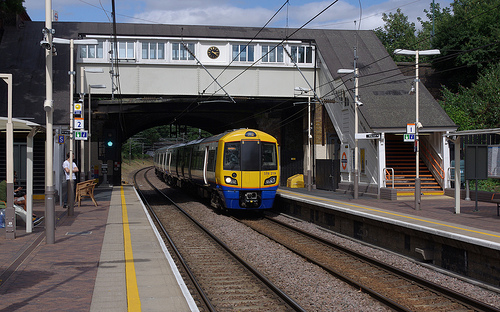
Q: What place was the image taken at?
A: It was taken at the train station.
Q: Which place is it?
A: It is a train station.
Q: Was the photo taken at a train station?
A: Yes, it was taken in a train station.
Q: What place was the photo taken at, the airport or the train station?
A: It was taken at the train station.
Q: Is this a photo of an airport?
A: No, the picture is showing a train station.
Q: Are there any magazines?
A: No, there are no magazines.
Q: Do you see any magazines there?
A: No, there are no magazines.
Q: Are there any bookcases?
A: No, there are no bookcases.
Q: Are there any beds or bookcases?
A: No, there are no bookcases or beds.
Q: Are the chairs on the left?
A: Yes, the chairs are on the left of the image.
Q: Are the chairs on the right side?
A: No, the chairs are on the left of the image.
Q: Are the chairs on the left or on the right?
A: The chairs are on the left of the image.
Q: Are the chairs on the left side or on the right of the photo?
A: The chairs are on the left of the image.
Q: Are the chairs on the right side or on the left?
A: The chairs are on the left of the image.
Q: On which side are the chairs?
A: The chairs are on the left of the image.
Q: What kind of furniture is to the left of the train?
A: The pieces of furniture are chairs.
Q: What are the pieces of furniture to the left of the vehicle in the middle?
A: The pieces of furniture are chairs.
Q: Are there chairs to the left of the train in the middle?
A: Yes, there are chairs to the left of the train.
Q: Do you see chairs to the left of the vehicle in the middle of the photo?
A: Yes, there are chairs to the left of the train.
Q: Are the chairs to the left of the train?
A: Yes, the chairs are to the left of the train.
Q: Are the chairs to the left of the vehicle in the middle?
A: Yes, the chairs are to the left of the train.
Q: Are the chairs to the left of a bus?
A: No, the chairs are to the left of the train.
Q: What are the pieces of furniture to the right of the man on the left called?
A: The pieces of furniture are chairs.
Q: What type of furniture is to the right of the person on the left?
A: The pieces of furniture are chairs.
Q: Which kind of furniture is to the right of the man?
A: The pieces of furniture are chairs.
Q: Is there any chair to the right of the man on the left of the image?
A: Yes, there are chairs to the right of the man.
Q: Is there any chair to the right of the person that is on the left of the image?
A: Yes, there are chairs to the right of the man.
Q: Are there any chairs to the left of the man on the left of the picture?
A: No, the chairs are to the right of the man.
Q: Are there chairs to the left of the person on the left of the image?
A: No, the chairs are to the right of the man.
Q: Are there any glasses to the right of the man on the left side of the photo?
A: No, there are chairs to the right of the man.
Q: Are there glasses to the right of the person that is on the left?
A: No, there are chairs to the right of the man.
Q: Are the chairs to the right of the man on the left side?
A: Yes, the chairs are to the right of the man.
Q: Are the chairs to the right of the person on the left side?
A: Yes, the chairs are to the right of the man.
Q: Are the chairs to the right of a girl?
A: No, the chairs are to the right of the man.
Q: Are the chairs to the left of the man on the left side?
A: No, the chairs are to the right of the man.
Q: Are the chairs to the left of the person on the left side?
A: No, the chairs are to the right of the man.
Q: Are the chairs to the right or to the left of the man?
A: The chairs are to the right of the man.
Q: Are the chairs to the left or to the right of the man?
A: The chairs are to the right of the man.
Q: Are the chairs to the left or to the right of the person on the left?
A: The chairs are to the right of the man.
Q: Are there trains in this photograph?
A: Yes, there is a train.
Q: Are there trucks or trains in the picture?
A: Yes, there is a train.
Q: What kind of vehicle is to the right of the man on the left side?
A: The vehicle is a train.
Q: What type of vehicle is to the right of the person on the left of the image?
A: The vehicle is a train.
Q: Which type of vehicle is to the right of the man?
A: The vehicle is a train.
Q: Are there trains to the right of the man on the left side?
A: Yes, there is a train to the right of the man.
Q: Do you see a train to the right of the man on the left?
A: Yes, there is a train to the right of the man.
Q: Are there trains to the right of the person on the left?
A: Yes, there is a train to the right of the man.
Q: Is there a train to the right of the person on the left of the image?
A: Yes, there is a train to the right of the man.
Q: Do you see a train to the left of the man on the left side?
A: No, the train is to the right of the man.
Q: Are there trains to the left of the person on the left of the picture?
A: No, the train is to the right of the man.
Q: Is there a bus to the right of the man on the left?
A: No, there is a train to the right of the man.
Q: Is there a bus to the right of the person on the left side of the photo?
A: No, there is a train to the right of the man.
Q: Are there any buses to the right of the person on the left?
A: No, there is a train to the right of the man.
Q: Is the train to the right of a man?
A: Yes, the train is to the right of a man.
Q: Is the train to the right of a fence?
A: No, the train is to the right of a man.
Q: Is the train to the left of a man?
A: No, the train is to the right of a man.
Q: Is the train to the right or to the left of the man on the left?
A: The train is to the right of the man.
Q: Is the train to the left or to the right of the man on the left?
A: The train is to the right of the man.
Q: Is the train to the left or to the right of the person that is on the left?
A: The train is to the right of the man.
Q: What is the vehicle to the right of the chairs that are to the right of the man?
A: The vehicle is a train.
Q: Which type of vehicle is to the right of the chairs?
A: The vehicle is a train.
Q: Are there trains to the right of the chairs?
A: Yes, there is a train to the right of the chairs.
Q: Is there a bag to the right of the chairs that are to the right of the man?
A: No, there is a train to the right of the chairs.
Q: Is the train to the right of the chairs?
A: Yes, the train is to the right of the chairs.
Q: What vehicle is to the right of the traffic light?
A: The vehicle is a train.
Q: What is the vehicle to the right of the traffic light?
A: The vehicle is a train.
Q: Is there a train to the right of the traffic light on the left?
A: Yes, there is a train to the right of the traffic signal.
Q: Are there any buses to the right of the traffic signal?
A: No, there is a train to the right of the traffic signal.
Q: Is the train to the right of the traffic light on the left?
A: Yes, the train is to the right of the traffic light.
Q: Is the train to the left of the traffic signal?
A: No, the train is to the right of the traffic signal.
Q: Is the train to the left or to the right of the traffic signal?
A: The train is to the right of the traffic signal.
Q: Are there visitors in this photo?
A: No, there are no visitors.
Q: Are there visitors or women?
A: No, there are no visitors or women.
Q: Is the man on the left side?
A: Yes, the man is on the left of the image.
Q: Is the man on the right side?
A: No, the man is on the left of the image.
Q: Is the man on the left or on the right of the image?
A: The man is on the left of the image.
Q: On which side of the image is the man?
A: The man is on the left of the image.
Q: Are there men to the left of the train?
A: Yes, there is a man to the left of the train.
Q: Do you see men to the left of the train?
A: Yes, there is a man to the left of the train.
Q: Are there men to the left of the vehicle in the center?
A: Yes, there is a man to the left of the train.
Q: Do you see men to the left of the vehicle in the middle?
A: Yes, there is a man to the left of the train.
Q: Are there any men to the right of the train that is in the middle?
A: No, the man is to the left of the train.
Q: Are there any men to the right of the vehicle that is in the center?
A: No, the man is to the left of the train.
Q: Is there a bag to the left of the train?
A: No, there is a man to the left of the train.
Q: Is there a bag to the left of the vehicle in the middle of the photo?
A: No, there is a man to the left of the train.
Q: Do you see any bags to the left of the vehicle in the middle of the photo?
A: No, there is a man to the left of the train.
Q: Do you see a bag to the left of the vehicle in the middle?
A: No, there is a man to the left of the train.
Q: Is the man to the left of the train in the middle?
A: Yes, the man is to the left of the train.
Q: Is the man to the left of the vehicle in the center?
A: Yes, the man is to the left of the train.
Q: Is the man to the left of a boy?
A: No, the man is to the left of the train.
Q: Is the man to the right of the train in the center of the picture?
A: No, the man is to the left of the train.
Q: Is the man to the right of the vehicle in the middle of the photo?
A: No, the man is to the left of the train.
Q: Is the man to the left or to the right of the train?
A: The man is to the left of the train.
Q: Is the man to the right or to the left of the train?
A: The man is to the left of the train.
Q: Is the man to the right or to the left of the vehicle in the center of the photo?
A: The man is to the left of the train.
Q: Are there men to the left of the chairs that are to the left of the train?
A: Yes, there is a man to the left of the chairs.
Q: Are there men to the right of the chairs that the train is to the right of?
A: No, the man is to the left of the chairs.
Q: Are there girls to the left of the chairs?
A: No, there is a man to the left of the chairs.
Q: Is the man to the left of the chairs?
A: Yes, the man is to the left of the chairs.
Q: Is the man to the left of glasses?
A: No, the man is to the left of the chairs.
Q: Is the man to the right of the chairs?
A: No, the man is to the left of the chairs.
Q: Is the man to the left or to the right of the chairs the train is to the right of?
A: The man is to the left of the chairs.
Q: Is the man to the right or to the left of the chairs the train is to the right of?
A: The man is to the left of the chairs.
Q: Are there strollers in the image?
A: No, there are no strollers.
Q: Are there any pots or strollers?
A: No, there are no strollers or pots.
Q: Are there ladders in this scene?
A: No, there are no ladders.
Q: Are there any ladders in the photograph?
A: No, there are no ladders.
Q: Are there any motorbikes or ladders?
A: No, there are no ladders or motorbikes.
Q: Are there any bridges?
A: Yes, there is a bridge.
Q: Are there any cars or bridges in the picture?
A: Yes, there is a bridge.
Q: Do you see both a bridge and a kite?
A: No, there is a bridge but no kites.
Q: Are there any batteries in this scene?
A: No, there are no batteries.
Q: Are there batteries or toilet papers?
A: No, there are no batteries or toilet papers.